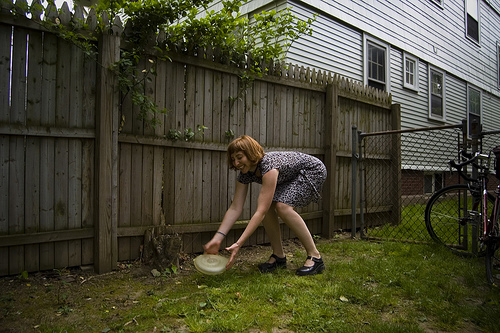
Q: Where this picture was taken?
A: In a backyard.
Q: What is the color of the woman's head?
A: Is red.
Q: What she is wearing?
A: A dress.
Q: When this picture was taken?
A: During the day.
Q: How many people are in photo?
A: One.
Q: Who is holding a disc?
A: A woman.